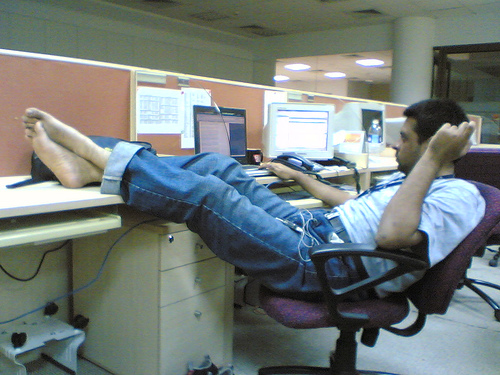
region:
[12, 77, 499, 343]
man sitting on chair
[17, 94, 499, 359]
man sitting on chair on comupter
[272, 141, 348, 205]
black phone on desk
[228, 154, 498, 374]
reclined swivel chair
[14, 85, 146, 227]
man bare feet on table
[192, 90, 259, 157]
black computer screen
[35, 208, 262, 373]
chest of drawers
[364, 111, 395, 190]
water bottle on table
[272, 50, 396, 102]
four lights on ceiling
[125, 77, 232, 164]
papers pinned on board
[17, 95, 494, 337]
Man lounging in chair.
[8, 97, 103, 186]
A man's bare feet.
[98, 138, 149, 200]
Cuff in man's blue jeans.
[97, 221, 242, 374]
Three drawers under desk.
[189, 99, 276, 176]
Lap top computer on desk.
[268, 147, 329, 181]
Phone sitting on desk.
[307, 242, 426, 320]
Black arm of chair.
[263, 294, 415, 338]
Purple seat of chair.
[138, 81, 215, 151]
Papers pinned to wall behind computer.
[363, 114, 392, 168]
Bottle of water sitting on desk.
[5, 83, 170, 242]
man with barefoot on a desk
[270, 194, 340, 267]
cellphone on mans lap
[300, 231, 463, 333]
black handle of chair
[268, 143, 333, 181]
black phone on desk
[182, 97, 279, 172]
black computer screen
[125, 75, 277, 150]
paper on board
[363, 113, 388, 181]
water bottle on table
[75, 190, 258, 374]
chest of drawers under table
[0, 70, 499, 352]
man sitting with legs on desk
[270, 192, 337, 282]
cellphone on mans lap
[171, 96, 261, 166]
black computer screen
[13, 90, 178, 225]
man with barefoot on desk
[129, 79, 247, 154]
papers on board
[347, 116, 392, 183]
water bottle on desk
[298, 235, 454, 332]
black arm rest of chair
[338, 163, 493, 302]
man has on white shirt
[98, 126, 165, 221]
mans jeans are rolled up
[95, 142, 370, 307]
mans is wearing jeans and they are way too high on his waist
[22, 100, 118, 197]
bare feet on desk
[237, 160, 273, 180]
man is typing on keyboard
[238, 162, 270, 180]
keyboard is white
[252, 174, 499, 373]
mans chair is reclining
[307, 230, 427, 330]
chair has black armrest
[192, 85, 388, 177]
there are three monitors visible on the desk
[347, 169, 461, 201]
man has blue lanyard around his neck